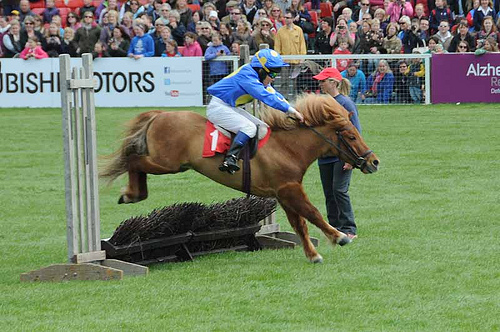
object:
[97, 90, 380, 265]
horse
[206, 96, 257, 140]
pants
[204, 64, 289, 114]
shirt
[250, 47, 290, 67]
helmet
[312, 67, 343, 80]
hat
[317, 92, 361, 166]
sweatshirt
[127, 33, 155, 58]
shirt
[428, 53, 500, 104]
sign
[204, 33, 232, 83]
person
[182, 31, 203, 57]
person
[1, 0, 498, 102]
audience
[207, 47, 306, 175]
rider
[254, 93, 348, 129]
mane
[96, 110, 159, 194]
tail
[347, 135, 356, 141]
eye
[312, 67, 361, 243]
person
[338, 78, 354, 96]
ponytail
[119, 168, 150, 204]
leg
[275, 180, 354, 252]
leg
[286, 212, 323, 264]
leg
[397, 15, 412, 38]
person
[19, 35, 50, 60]
person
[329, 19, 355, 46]
person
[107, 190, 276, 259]
item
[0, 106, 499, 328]
ground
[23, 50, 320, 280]
fence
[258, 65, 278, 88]
head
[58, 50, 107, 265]
gate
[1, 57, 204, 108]
sign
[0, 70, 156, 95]
lettering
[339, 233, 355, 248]
hoof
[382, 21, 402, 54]
spectator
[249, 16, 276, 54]
spectator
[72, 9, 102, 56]
spectator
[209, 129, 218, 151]
number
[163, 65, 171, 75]
logo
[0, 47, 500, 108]
fence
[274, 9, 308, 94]
man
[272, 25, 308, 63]
shirt